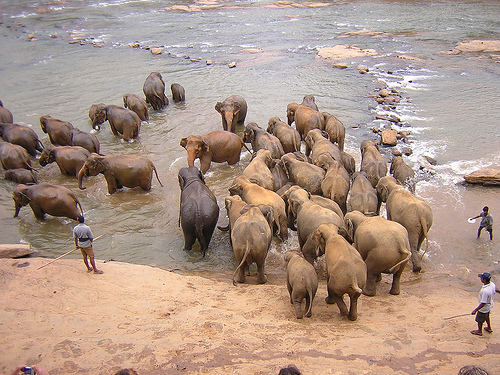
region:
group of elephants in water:
[17, 61, 435, 319]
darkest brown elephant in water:
[165, 158, 223, 262]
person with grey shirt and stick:
[38, 209, 146, 314]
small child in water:
[463, 207, 493, 244]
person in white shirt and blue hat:
[439, 271, 498, 350]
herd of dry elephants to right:
[219, 101, 421, 321]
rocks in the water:
[375, 85, 430, 151]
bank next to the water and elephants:
[13, 272, 468, 362]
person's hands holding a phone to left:
[10, 355, 47, 373]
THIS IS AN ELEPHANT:
[14, 187, 89, 224]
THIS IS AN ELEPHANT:
[66, 158, 158, 187]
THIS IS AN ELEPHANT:
[35, 151, 88, 169]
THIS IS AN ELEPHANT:
[44, 107, 76, 146]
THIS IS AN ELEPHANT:
[66, 125, 103, 144]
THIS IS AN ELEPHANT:
[104, 110, 140, 132]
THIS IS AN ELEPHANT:
[121, 90, 145, 114]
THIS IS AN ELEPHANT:
[143, 70, 175, 112]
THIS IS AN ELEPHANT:
[219, 91, 244, 136]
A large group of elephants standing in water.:
[0, 0, 499, 372]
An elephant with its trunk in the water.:
[13, 183, 83, 223]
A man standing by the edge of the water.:
[72, 212, 104, 273]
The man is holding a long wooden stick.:
[35, 212, 105, 273]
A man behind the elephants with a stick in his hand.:
[441, 270, 496, 333]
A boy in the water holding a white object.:
[465, 205, 495, 244]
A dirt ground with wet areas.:
[0, 255, 499, 373]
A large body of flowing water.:
[0, 0, 498, 275]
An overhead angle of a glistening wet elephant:
[173, 165, 220, 260]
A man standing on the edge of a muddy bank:
[66, 218, 116, 279]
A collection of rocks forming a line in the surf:
[366, 65, 413, 146]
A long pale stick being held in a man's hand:
[25, 241, 80, 274]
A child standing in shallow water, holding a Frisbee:
[466, 203, 496, 240]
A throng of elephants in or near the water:
[175, 96, 434, 316]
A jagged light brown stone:
[455, 159, 498, 187]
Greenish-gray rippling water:
[253, 63, 298, 95]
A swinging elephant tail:
[227, 244, 265, 289]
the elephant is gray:
[179, 169, 218, 254]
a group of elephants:
[1, 69, 433, 321]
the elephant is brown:
[316, 225, 366, 323]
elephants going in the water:
[1, 2, 433, 323]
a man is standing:
[72, 215, 102, 275]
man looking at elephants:
[472, 273, 494, 335]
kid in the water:
[470, 208, 492, 241]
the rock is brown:
[463, 165, 498, 185]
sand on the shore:
[1, 256, 498, 372]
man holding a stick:
[38, 217, 105, 274]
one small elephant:
[168, 75, 189, 108]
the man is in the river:
[462, 198, 494, 244]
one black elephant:
[172, 165, 222, 256]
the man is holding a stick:
[68, 215, 104, 270]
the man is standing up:
[70, 215, 105, 276]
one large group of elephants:
[175, 80, 436, 311]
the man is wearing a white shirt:
[448, 265, 498, 331]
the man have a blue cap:
[461, 260, 495, 343]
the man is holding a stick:
[36, 216, 106, 271]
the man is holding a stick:
[443, 270, 498, 334]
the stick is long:
[38, 232, 106, 270]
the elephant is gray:
[283, 248, 317, 318]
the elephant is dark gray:
[177, 163, 218, 259]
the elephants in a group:
[0, 71, 432, 320]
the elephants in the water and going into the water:
[1, 0, 499, 320]